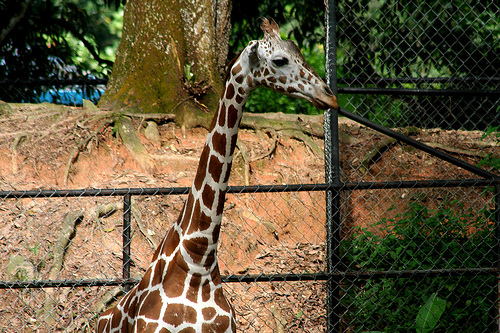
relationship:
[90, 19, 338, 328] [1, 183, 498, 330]
giraffe by fencing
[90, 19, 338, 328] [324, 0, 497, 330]
giraffe by fencing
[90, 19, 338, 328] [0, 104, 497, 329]
giraffe by hill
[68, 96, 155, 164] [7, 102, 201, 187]
roots spreading in soil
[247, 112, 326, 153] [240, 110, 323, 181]
roots spreading in soil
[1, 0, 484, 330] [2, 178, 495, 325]
wires over poles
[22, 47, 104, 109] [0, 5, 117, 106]
bluecar behind leaves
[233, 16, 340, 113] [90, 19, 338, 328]
giraffe's head attached to giraffe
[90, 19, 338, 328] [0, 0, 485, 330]
giraffe inside of fenced area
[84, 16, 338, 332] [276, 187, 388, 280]
giraffe standing behind fence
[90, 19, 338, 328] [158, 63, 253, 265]
giraffe has neck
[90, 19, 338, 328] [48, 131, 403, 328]
giraffe behind fence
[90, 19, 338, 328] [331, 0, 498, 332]
giraffe behind fence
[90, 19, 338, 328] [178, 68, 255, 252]
giraffe with neck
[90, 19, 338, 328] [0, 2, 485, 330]
giraffe behind fence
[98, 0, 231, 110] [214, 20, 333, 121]
tree trunk behind giraffe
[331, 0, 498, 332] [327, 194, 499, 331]
fence protecting plants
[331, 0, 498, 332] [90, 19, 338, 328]
fence protecting giraffe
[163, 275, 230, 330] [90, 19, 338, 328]
spots on giraffe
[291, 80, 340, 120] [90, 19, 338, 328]
mouth of giraffe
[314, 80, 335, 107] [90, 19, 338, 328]
nose of giraffe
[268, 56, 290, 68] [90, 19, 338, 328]
eye of giraffe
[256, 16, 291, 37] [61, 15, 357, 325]
horns of giraffe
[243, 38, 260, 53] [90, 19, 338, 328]
ear of giraffe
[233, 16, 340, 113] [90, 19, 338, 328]
giraffe's head of giraffe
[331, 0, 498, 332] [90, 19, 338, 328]
fence behind giraffe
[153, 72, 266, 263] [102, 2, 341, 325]
giraffe neck of giraffe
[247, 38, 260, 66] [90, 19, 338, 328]
ear of giraffe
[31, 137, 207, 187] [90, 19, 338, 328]
dirt behind giraffe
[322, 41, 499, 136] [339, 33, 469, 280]
leaves behind fence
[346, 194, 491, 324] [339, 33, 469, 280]
leaves behind fence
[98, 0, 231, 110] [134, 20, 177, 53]
tree trunk covered with spots